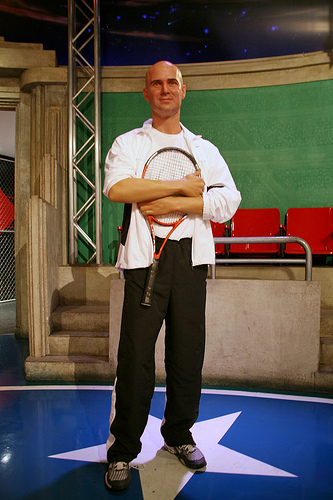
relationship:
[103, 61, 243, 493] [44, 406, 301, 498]
andre agassi standing on star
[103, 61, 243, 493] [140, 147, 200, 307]
andre agassi hugging racket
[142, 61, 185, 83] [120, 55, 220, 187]
head of man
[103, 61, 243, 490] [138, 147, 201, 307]
andre agassi holding racket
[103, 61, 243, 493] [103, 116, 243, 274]
andre agassi wearing white jacket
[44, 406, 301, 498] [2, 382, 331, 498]
star on floor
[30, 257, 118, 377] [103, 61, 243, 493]
steps behind andre agassi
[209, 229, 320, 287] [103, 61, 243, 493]
metal railing behind andre agassi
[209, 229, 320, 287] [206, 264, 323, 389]
metal railing on top of wall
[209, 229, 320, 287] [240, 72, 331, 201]
metal railing on top of wall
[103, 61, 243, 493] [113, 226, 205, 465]
andre agassi wearing black pants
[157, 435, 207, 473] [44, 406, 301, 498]
foot on star